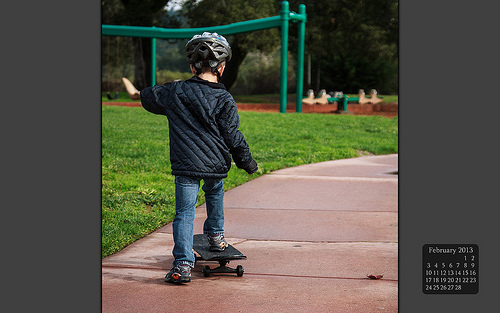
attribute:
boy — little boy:
[112, 25, 267, 246]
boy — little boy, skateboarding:
[118, 27, 259, 292]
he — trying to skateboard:
[123, 30, 255, 289]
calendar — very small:
[419, 244, 479, 294]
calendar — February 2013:
[420, 240, 478, 294]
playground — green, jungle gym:
[104, 3, 309, 119]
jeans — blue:
[149, 173, 235, 283]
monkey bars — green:
[116, 16, 316, 116]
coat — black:
[130, 70, 263, 184]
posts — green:
[265, 11, 314, 98]